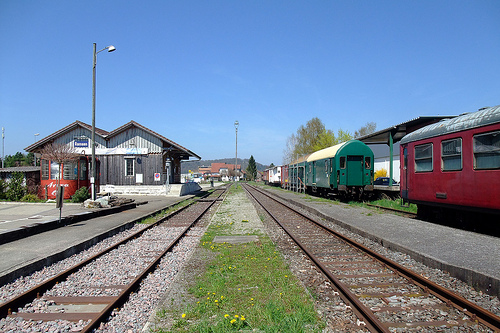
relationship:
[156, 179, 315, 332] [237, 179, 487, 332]
grass between tracks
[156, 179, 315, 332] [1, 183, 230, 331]
grass between tracks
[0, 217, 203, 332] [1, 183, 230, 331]
rocks on railroad tracks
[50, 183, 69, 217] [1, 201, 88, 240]
sign in parking lot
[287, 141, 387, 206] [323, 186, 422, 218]
train car on tracks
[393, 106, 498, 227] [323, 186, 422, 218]
train car on tracks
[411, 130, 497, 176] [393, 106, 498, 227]
windows in a row on train car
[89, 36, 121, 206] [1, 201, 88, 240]
light in parking lot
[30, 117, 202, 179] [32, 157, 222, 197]
building on platform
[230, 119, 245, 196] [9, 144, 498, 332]
light between railroad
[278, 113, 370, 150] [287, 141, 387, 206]
trees over train car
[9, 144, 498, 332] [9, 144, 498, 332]
railroad of a railroad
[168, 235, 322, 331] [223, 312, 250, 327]
grass have yellow flowers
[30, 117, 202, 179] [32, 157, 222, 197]
building near platform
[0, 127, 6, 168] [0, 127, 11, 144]
lights with lights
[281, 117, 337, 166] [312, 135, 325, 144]
trees with green leaves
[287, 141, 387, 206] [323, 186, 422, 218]
train car parked on tracks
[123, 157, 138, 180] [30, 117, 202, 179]
window of building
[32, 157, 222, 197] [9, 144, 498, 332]
platform near railroad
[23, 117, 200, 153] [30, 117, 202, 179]
roof of building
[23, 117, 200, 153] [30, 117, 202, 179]
roof double on building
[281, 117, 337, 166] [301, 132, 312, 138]
trees tops are green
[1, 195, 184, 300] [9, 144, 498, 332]
sidewalk next to railroad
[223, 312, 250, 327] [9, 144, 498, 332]
flowers beside railroad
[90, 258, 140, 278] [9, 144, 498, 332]
gravel on railroad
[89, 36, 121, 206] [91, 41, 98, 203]
light on metal pole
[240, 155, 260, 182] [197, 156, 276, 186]
pine tree in distance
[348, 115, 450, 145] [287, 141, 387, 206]
awning beside train car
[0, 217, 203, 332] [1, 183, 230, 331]
rocks on tracks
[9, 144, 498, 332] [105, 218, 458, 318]
railroad in a set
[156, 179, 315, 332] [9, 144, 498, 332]
grass on train railroad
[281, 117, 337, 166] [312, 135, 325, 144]
trees green and has leaves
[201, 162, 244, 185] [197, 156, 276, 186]
buildings in distance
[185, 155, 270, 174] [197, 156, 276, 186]
mountain range in distance